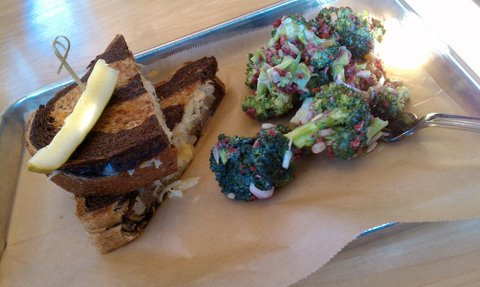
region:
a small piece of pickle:
[26, 44, 115, 180]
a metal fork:
[386, 98, 475, 164]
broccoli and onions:
[229, 10, 407, 208]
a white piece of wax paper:
[0, 30, 464, 267]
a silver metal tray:
[2, 1, 478, 266]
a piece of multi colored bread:
[30, 28, 147, 166]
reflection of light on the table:
[12, 2, 169, 45]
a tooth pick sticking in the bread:
[30, 24, 91, 95]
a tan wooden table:
[28, 2, 173, 44]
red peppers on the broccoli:
[231, 5, 350, 135]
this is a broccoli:
[217, 135, 280, 194]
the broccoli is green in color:
[214, 127, 283, 195]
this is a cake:
[123, 65, 203, 192]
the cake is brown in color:
[115, 77, 208, 183]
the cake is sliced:
[123, 93, 160, 162]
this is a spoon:
[427, 106, 472, 147]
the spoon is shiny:
[431, 111, 470, 137]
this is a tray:
[436, 49, 453, 69]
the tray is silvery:
[417, 30, 441, 51]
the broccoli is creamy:
[257, 15, 358, 115]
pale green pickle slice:
[28, 56, 121, 174]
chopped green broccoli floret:
[207, 128, 293, 202]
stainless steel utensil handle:
[384, 103, 477, 150]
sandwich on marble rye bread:
[26, 32, 173, 183]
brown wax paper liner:
[181, 183, 413, 272]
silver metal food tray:
[5, 8, 467, 265]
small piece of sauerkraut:
[157, 174, 201, 201]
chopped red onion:
[248, 178, 274, 199]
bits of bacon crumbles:
[261, 34, 296, 66]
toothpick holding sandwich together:
[44, 33, 89, 94]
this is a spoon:
[380, 117, 478, 132]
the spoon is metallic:
[397, 109, 476, 137]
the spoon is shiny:
[393, 113, 478, 136]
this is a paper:
[241, 202, 420, 261]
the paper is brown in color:
[267, 211, 330, 251]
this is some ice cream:
[242, 15, 410, 158]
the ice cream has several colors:
[265, 34, 378, 133]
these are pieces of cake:
[8, 52, 210, 235]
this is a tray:
[1, 108, 27, 170]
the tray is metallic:
[9, 106, 24, 159]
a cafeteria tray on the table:
[0, 1, 479, 284]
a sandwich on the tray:
[25, 34, 223, 254]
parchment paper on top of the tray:
[200, 199, 478, 285]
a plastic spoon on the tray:
[382, 109, 478, 141]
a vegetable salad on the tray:
[212, 7, 409, 201]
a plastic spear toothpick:
[51, 34, 84, 92]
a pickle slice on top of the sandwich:
[29, 59, 119, 175]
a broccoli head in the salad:
[286, 84, 371, 157]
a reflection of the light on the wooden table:
[26, 1, 87, 38]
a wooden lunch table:
[0, 1, 53, 86]